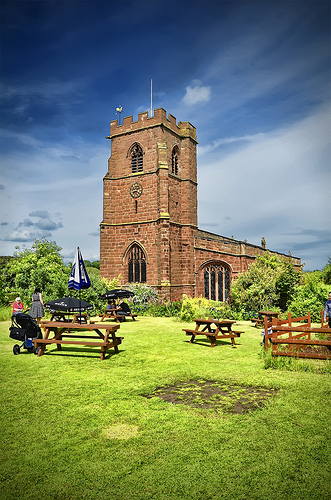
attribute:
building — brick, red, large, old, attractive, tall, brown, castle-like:
[98, 105, 306, 317]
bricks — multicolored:
[147, 222, 188, 286]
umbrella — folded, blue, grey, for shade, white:
[66, 244, 91, 292]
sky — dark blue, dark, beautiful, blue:
[1, 2, 330, 263]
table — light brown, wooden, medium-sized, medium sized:
[29, 310, 123, 366]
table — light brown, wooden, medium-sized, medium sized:
[176, 309, 246, 354]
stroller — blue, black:
[8, 309, 45, 358]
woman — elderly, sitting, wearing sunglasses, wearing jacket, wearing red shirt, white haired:
[10, 296, 26, 319]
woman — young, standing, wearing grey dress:
[26, 284, 47, 320]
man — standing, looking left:
[322, 279, 330, 335]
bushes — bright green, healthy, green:
[0, 238, 331, 318]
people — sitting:
[98, 298, 135, 321]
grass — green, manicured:
[0, 313, 331, 499]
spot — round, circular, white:
[98, 418, 143, 446]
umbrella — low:
[44, 297, 94, 315]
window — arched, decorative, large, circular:
[127, 139, 148, 177]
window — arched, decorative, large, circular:
[120, 239, 150, 288]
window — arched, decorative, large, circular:
[168, 143, 185, 179]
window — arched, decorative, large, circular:
[197, 259, 233, 305]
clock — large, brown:
[126, 183, 145, 199]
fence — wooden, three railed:
[266, 306, 330, 362]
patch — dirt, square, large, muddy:
[136, 371, 287, 418]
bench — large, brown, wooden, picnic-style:
[32, 337, 114, 349]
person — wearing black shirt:
[118, 300, 131, 312]